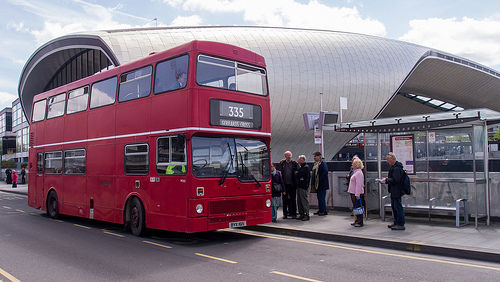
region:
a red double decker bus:
[15, 54, 273, 261]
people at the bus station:
[263, 93, 438, 240]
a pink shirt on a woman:
[347, 167, 364, 198]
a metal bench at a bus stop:
[374, 178, 472, 227]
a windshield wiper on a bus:
[217, 138, 235, 184]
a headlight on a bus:
[195, 200, 207, 216]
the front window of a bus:
[195, 134, 236, 180]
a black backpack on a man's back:
[402, 166, 413, 197]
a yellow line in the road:
[1, 266, 22, 280]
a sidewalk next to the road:
[271, 197, 497, 251]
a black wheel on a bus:
[126, 191, 146, 238]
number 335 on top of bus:
[215, 93, 270, 128]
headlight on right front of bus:
[191, 193, 223, 223]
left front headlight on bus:
[248, 183, 290, 225]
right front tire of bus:
[122, 187, 189, 241]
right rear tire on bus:
[40, 187, 92, 224]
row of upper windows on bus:
[43, 55, 190, 106]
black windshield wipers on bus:
[216, 145, 267, 192]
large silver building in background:
[43, 28, 430, 106]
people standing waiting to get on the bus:
[278, 148, 418, 220]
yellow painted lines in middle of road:
[205, 239, 296, 280]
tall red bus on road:
[13, 39, 274, 227]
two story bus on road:
[18, 45, 275, 231]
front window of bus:
[192, 138, 269, 180]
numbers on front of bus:
[195, 98, 261, 134]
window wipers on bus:
[197, 138, 272, 188]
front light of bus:
[182, 199, 207, 214]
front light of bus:
[255, 193, 278, 210]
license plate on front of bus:
[226, 217, 253, 229]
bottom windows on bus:
[33, 146, 173, 179]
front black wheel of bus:
[120, 199, 141, 225]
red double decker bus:
[27, 38, 278, 242]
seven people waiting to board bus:
[269, 148, 410, 231]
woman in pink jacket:
[342, 156, 371, 228]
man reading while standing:
[372, 152, 415, 229]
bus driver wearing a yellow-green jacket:
[161, 153, 190, 180]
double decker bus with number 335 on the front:
[201, 88, 268, 136]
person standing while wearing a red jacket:
[5, 167, 21, 189]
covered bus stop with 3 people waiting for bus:
[327, 118, 499, 234]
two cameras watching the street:
[298, 101, 343, 136]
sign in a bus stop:
[388, 135, 416, 155]